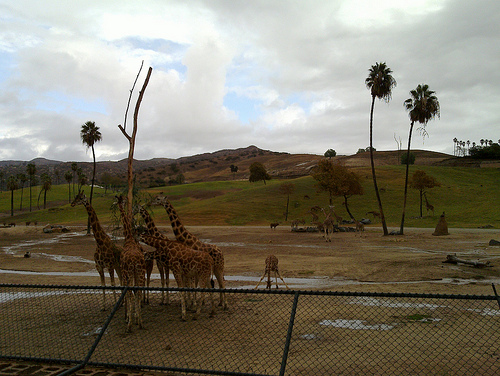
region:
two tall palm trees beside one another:
[360, 62, 442, 242]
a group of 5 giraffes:
[63, 187, 228, 312]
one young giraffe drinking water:
[248, 254, 289, 290]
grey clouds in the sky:
[184, 37, 334, 125]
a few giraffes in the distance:
[302, 190, 371, 247]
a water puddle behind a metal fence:
[318, 306, 397, 341]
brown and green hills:
[175, 142, 408, 214]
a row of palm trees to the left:
[6, 161, 96, 206]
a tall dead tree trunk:
[117, 60, 154, 237]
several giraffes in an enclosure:
[14, 57, 497, 352]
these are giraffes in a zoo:
[56, 135, 248, 350]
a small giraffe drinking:
[249, 246, 307, 304]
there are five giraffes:
[54, 155, 316, 330]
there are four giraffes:
[58, 167, 232, 318]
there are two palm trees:
[350, 60, 443, 245]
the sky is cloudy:
[216, 70, 338, 130]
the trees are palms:
[345, 56, 442, 250]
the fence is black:
[313, 282, 437, 366]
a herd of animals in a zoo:
[36, 107, 398, 364]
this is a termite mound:
[416, 202, 465, 243]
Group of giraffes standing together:
[70, 187, 219, 281]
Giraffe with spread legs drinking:
[254, 250, 293, 284]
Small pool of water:
[279, 273, 342, 283]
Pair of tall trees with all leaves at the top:
[361, 58, 437, 239]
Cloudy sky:
[28, 17, 328, 72]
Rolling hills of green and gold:
[138, 152, 314, 215]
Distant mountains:
[8, 154, 66, 169]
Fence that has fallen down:
[30, 282, 112, 352]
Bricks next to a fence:
[1, 362, 96, 370]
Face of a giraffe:
[64, 187, 93, 211]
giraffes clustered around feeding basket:
[60, 146, 271, 334]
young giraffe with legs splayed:
[246, 247, 291, 293]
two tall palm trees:
[365, 55, 430, 250]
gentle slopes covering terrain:
[20, 131, 480, 256]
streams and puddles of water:
[7, 201, 472, 327]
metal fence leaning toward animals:
[5, 275, 485, 365]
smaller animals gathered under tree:
[257, 152, 367, 242]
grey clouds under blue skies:
[66, 17, 451, 108]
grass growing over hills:
[20, 175, 462, 210]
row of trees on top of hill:
[440, 130, 498, 166]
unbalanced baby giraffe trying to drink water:
[251, 252, 291, 293]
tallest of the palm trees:
[360, 60, 390, 235]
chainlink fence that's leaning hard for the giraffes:
[0, 285, 499, 370]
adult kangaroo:
[315, 200, 335, 240]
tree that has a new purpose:
[115, 55, 151, 215]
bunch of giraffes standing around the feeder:
[65, 185, 230, 335]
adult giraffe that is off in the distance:
[420, 185, 435, 215]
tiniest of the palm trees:
[272, 177, 297, 223]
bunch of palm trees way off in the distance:
[450, 135, 497, 157]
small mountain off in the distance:
[209, 138, 293, 163]